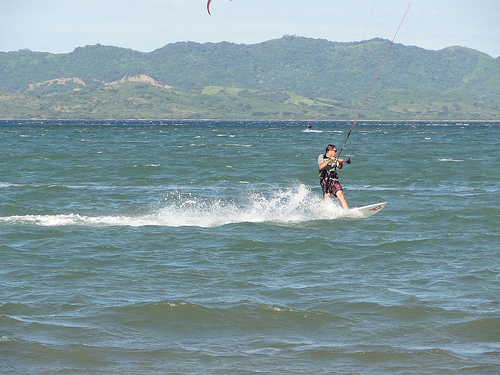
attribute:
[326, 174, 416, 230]
board — white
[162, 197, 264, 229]
wave — small 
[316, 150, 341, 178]
shirt — grey 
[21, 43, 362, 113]
trees — green 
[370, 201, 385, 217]
logo — red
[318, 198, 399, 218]
board — surf, white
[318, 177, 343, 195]
swim trunks — red, blue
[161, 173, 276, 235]
spray — white 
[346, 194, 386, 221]
wake — white 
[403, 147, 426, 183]
water — blue , choppy  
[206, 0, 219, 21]
kite — red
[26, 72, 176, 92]
stone — tan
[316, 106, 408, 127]
shoreline — empty  , long 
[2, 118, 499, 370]
water — blue, dark, shiny, brown, choppy